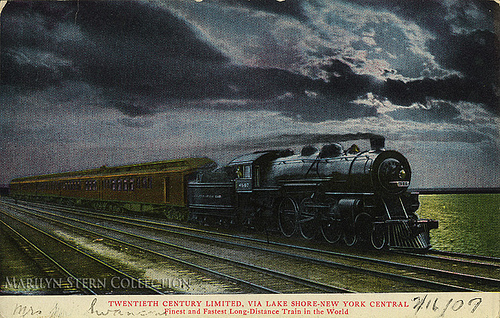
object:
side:
[211, 171, 233, 181]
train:
[0, 131, 442, 256]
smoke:
[236, 131, 371, 146]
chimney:
[366, 133, 384, 150]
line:
[0, 198, 499, 293]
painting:
[3, 0, 499, 298]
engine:
[187, 139, 439, 253]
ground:
[0, 189, 499, 294]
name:
[0, 273, 196, 295]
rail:
[0, 190, 499, 295]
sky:
[0, 0, 499, 190]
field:
[419, 190, 498, 257]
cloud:
[0, 0, 499, 187]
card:
[0, 291, 499, 317]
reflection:
[336, 52, 399, 120]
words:
[105, 299, 409, 316]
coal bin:
[184, 162, 240, 219]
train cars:
[0, 157, 220, 227]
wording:
[6, 266, 196, 292]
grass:
[414, 190, 498, 260]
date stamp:
[406, 292, 485, 317]